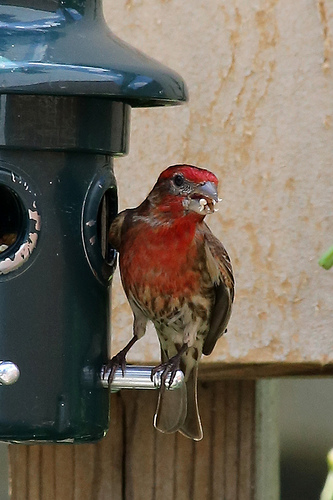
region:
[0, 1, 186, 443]
black and silver bird feeder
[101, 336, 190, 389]
brown feet on the bird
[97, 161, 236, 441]
red and brown bird on the feeder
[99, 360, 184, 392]
silver stick for the bird to sit on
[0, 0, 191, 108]
black bird feeder top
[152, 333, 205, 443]
the bird's tail feathers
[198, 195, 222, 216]
bird feed in the bird's mouth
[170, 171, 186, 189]
eye on the bird's head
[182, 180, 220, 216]
beak on the bird's head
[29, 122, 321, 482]
The bird is sitting at a feeder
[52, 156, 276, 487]
The bird is watching for predators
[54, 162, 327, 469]
The bird is sitting on a perch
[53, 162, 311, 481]
The bird is out in the daytime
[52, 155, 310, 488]
The bird has very sharp claws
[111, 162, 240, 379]
Bird perching on support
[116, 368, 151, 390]
Wide shiny elevated support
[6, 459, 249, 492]
A brown wooden fence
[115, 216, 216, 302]
Patch of red on bird body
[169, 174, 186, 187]
Small sharp black eye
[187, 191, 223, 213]
Bird eating some twigs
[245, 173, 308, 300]
Coarse paint tinted wall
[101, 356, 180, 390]
Long sharp bird claws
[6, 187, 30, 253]
Circular shape on tube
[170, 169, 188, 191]
a right bird eye.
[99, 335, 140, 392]
a right bird claw.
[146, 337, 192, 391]
A left bird claw.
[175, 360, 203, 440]
a long tail wing.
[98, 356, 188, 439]
a shiney metal object.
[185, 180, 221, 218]
a small bird's beak.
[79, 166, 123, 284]
a hole on a bird feeder.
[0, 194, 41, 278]
chipped paint on a bird feeder.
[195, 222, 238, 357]
a left wing on a bird.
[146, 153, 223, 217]
the head of a small bird.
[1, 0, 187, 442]
side of bird feeder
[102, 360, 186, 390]
two feet on perch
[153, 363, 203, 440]
tail feathers of bird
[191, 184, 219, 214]
food in bird beak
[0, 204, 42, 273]
metal with worn off paint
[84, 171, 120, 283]
round hole in bird feeder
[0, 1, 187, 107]
shiny cover of bird feeder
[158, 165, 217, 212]
red top of bird head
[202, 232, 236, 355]
wing on side of bird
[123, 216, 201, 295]
red chest of bird